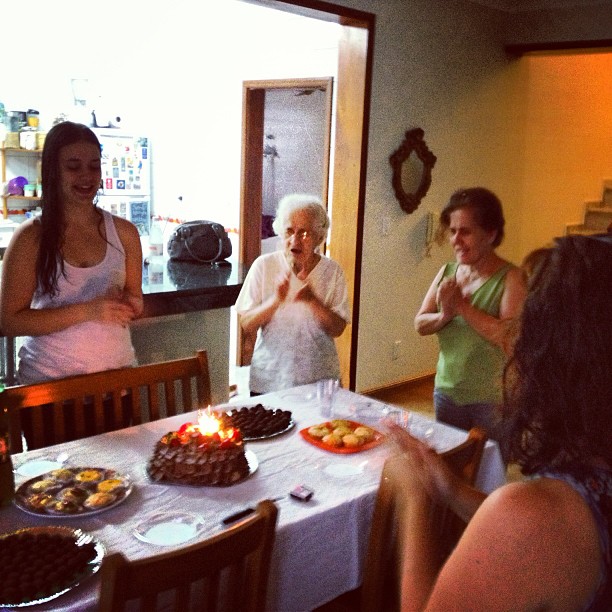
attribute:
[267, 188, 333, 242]
hair — white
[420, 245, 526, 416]
shirt — green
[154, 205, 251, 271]
purse — large, black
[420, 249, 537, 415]
top — woman's, green, tank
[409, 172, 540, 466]
woman — standing inside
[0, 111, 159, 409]
woman — standing inside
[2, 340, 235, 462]
bench — wooden, for table seating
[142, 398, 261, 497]
cake — lighted, birthday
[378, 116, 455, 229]
mirror — small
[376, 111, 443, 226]
frame — dark, wooden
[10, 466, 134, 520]
plate — made for dining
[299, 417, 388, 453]
plate — made for dining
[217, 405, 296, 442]
plate — made for dining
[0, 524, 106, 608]
plate — made for dining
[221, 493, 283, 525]
utensil — made for dining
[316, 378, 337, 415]
vessel — made for dining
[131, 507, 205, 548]
plate — made for dining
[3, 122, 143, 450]
person — standing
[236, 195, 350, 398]
person — standing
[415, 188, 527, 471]
person — standing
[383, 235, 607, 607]
person — standing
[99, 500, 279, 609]
chair — you sit in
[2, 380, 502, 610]
tablecloth — white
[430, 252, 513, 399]
top — green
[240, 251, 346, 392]
shirt — white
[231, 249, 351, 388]
shirt — white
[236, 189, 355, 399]
woman — elderly, hand-clapping, older, grey-haired, clapping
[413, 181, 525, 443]
woman — hand-clapping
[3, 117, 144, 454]
woman — smiling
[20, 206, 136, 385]
tank top — white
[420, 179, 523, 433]
woman — hand-clapping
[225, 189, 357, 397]
woman — hand-clapping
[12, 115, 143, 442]
woman — young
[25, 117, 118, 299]
hair — long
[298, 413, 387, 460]
plate — red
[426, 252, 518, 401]
shirt — green